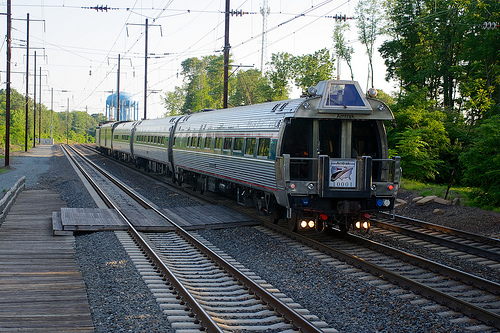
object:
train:
[93, 80, 406, 236]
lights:
[300, 219, 371, 230]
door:
[280, 117, 383, 183]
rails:
[283, 153, 402, 168]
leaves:
[380, 28, 500, 80]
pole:
[221, 0, 232, 109]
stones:
[71, 143, 205, 208]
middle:
[120, 165, 364, 333]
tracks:
[332, 218, 499, 333]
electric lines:
[0, 0, 363, 93]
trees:
[161, 54, 343, 117]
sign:
[329, 159, 357, 189]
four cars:
[94, 97, 304, 203]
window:
[256, 136, 272, 157]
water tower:
[104, 91, 139, 122]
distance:
[0, 0, 154, 132]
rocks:
[75, 230, 174, 332]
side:
[0, 119, 107, 333]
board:
[51, 202, 261, 235]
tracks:
[61, 143, 330, 332]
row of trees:
[0, 86, 116, 150]